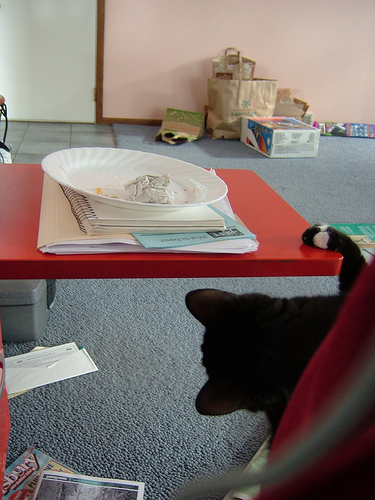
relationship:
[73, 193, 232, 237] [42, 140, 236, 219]
notebook under plate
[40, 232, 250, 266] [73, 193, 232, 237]
papers under notebook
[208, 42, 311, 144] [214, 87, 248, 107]
bags ae brown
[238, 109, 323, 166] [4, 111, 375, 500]
box on floor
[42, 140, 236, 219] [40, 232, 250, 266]
plate on papers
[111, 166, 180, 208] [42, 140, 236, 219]
napkin on plate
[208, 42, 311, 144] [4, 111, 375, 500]
bags on floor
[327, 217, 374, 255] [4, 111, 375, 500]
newspaper on floor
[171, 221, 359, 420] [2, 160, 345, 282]
cat on table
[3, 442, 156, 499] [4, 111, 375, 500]
magazine on floor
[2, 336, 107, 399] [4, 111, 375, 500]
mail on floor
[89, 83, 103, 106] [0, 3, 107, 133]
hinges on door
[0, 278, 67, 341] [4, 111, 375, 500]
tackle box on floor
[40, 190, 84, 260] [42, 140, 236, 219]
folder under plate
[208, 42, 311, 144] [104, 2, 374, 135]
bags against wall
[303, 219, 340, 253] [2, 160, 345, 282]
paw on table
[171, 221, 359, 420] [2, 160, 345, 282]
cat under table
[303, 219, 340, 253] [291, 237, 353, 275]
paw on corner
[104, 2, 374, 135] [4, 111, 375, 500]
wall and floor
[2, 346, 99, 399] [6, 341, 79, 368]
envelope with contents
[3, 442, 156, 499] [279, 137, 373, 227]
magazine on carpet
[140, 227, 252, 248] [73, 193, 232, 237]
paper in notebook